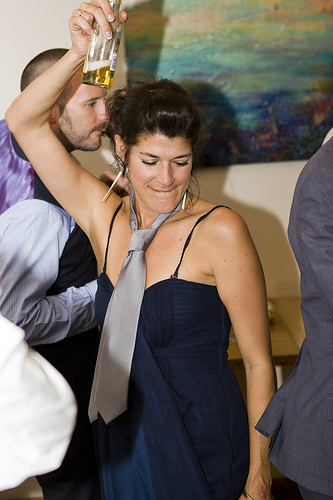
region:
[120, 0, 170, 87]
A shadow on the wall.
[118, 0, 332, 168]
A painting on the wall.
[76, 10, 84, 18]
A ring on a person's finger.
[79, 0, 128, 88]
A glass beverage bottle.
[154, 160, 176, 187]
The nose of a woman.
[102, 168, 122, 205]
A earring in a woman's ear.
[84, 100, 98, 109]
The eye of a man.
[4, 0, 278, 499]
A woman wearing a dress.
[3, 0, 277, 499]
A woman wearing a tie.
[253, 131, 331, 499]
A person wearing a suit.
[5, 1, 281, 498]
Woman drinking out of a bottle.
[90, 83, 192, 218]
Gold earrings on the woman.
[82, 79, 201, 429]
Woman wearing a gray tie.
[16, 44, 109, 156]
Beard on the man.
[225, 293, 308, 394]
Desk in the background.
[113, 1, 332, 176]
Painting on the wall.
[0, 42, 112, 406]
Purple and black vest on the man.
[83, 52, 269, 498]
Navy colored dress on the woman.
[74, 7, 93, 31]
Ring on the finger.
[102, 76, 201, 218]
Brown hair on the woman.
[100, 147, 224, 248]
woman is wearing earings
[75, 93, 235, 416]
woman wearing a tie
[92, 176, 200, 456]
woman wearing a tie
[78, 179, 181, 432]
the tie is silver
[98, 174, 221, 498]
the tie is silver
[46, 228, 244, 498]
the dress is blue